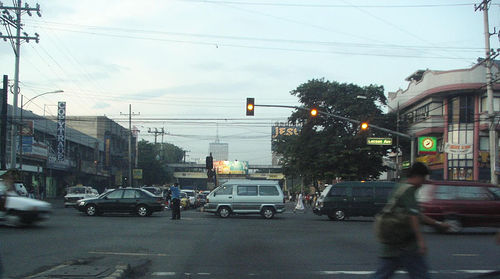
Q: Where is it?
A: This is at the road.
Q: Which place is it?
A: It is a road.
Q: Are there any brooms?
A: No, there are no brooms.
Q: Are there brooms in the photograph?
A: No, there are no brooms.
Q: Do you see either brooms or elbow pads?
A: No, there are no brooms or elbow pads.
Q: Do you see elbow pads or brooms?
A: No, there are no brooms or elbow pads.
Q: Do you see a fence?
A: No, there are no fences.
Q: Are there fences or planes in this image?
A: No, there are no fences or planes.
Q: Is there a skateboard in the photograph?
A: No, there are no skateboards.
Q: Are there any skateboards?
A: No, there are no skateboards.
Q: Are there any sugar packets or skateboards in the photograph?
A: No, there are no skateboards or sugar packets.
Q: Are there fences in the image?
A: No, there are no fences.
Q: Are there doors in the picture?
A: Yes, there is a door.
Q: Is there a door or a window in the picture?
A: Yes, there is a door.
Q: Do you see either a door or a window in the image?
A: Yes, there is a door.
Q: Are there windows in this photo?
A: Yes, there are windows.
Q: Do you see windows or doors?
A: Yes, there are windows.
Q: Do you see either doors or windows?
A: Yes, there are windows.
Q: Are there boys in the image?
A: No, there are no boys.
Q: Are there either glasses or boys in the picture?
A: No, there are no boys or glasses.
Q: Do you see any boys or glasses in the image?
A: No, there are no boys or glasses.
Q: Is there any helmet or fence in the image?
A: No, there are no fences or helmets.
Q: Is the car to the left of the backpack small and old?
A: Yes, the car is small and old.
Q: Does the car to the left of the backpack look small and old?
A: Yes, the car is small and old.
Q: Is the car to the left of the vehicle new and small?
A: No, the car is small but old.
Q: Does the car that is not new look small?
A: Yes, the car is small.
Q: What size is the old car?
A: The car is small.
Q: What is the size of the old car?
A: The car is small.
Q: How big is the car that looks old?
A: The car is small.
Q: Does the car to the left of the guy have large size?
A: No, the car is small.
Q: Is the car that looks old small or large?
A: The car is small.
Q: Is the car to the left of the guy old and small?
A: Yes, the car is old and small.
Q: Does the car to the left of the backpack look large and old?
A: No, the car is old but small.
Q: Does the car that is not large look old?
A: Yes, the car is old.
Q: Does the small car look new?
A: No, the car is old.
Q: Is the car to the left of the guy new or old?
A: The car is old.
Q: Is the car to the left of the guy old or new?
A: The car is old.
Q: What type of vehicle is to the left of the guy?
A: The vehicle is a car.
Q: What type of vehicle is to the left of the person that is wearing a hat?
A: The vehicle is a car.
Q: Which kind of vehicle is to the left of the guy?
A: The vehicle is a car.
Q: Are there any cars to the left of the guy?
A: Yes, there is a car to the left of the guy.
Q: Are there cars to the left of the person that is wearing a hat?
A: Yes, there is a car to the left of the guy.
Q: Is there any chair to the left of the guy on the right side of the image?
A: No, there is a car to the left of the guy.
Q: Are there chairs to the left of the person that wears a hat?
A: No, there is a car to the left of the guy.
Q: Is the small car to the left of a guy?
A: Yes, the car is to the left of a guy.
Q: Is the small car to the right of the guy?
A: No, the car is to the left of the guy.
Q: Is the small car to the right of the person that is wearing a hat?
A: No, the car is to the left of the guy.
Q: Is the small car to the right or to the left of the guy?
A: The car is to the left of the guy.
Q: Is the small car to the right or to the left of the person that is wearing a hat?
A: The car is to the left of the guy.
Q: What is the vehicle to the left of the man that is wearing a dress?
A: The vehicle is a car.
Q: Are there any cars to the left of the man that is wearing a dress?
A: Yes, there is a car to the left of the man.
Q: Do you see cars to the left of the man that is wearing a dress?
A: Yes, there is a car to the left of the man.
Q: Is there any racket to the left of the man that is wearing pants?
A: No, there is a car to the left of the man.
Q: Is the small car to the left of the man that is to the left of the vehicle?
A: Yes, the car is to the left of the man.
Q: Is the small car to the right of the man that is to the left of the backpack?
A: No, the car is to the left of the man.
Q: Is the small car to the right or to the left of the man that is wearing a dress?
A: The car is to the left of the man.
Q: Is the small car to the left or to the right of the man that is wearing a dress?
A: The car is to the left of the man.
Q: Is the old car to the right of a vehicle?
A: No, the car is to the left of a vehicle.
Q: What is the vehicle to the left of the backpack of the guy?
A: The vehicle is a car.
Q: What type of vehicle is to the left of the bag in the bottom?
A: The vehicle is a car.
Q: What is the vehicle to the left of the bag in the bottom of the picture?
A: The vehicle is a car.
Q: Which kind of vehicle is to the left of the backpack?
A: The vehicle is a car.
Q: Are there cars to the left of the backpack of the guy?
A: Yes, there is a car to the left of the backpack.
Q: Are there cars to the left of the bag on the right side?
A: Yes, there is a car to the left of the backpack.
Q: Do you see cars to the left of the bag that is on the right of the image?
A: Yes, there is a car to the left of the backpack.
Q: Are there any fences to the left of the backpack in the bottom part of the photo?
A: No, there is a car to the left of the backpack.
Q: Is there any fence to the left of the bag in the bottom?
A: No, there is a car to the left of the backpack.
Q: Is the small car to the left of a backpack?
A: Yes, the car is to the left of a backpack.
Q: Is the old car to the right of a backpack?
A: No, the car is to the left of a backpack.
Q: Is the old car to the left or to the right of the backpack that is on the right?
A: The car is to the left of the backpack.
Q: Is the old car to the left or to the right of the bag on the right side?
A: The car is to the left of the backpack.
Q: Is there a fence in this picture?
A: No, there are no fences.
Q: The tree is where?
A: The tree is on the roadside.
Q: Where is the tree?
A: The tree is on the roadside.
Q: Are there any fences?
A: No, there are no fences.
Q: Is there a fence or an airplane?
A: No, there are no fences or airplanes.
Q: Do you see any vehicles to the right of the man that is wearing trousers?
A: Yes, there is a vehicle to the right of the man.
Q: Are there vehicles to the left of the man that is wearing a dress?
A: No, the vehicle is to the right of the man.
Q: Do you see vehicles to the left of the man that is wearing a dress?
A: No, the vehicle is to the right of the man.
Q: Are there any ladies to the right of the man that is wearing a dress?
A: No, there is a vehicle to the right of the man.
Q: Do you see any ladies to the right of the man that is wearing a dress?
A: No, there is a vehicle to the right of the man.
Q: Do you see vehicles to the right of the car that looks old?
A: Yes, there is a vehicle to the right of the car.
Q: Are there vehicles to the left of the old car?
A: No, the vehicle is to the right of the car.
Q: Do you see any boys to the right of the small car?
A: No, there is a vehicle to the right of the car.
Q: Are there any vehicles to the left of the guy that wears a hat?
A: Yes, there is a vehicle to the left of the guy.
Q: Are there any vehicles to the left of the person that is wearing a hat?
A: Yes, there is a vehicle to the left of the guy.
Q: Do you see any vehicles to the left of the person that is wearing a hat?
A: Yes, there is a vehicle to the left of the guy.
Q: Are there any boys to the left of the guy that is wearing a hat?
A: No, there is a vehicle to the left of the guy.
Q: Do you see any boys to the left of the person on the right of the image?
A: No, there is a vehicle to the left of the guy.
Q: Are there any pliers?
A: No, there are no pliers.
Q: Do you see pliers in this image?
A: No, there are no pliers.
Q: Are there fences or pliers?
A: No, there are no pliers or fences.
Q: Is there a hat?
A: Yes, there is a hat.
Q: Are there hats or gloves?
A: Yes, there is a hat.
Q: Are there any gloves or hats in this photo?
A: Yes, there is a hat.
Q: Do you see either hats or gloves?
A: Yes, there is a hat.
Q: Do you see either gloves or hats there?
A: Yes, there is a hat.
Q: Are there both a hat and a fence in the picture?
A: No, there is a hat but no fences.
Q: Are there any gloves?
A: No, there are no gloves.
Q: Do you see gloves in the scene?
A: No, there are no gloves.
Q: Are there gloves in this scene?
A: No, there are no gloves.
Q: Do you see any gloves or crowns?
A: No, there are no gloves or crowns.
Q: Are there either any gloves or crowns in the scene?
A: No, there are no gloves or crowns.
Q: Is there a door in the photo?
A: Yes, there are doors.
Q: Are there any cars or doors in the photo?
A: Yes, there are doors.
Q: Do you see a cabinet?
A: No, there are no cabinets.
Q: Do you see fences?
A: No, there are no fences.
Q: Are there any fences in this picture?
A: No, there are no fences.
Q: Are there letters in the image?
A: Yes, there are letters.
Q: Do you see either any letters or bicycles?
A: Yes, there are letters.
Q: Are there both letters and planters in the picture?
A: No, there are letters but no planters.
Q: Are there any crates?
A: No, there are no crates.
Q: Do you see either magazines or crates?
A: No, there are no crates or magazines.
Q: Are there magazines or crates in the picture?
A: No, there are no crates or magazines.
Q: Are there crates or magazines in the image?
A: No, there are no crates or magazines.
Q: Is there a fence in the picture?
A: No, there are no fences.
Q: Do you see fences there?
A: No, there are no fences.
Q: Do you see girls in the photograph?
A: No, there are no girls.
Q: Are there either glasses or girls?
A: No, there are no girls or glasses.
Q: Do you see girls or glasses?
A: No, there are no girls or glasses.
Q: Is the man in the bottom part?
A: Yes, the man is in the bottom of the image.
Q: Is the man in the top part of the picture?
A: No, the man is in the bottom of the image.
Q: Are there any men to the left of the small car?
A: Yes, there is a man to the left of the car.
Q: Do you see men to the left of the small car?
A: Yes, there is a man to the left of the car.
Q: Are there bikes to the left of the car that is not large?
A: No, there is a man to the left of the car.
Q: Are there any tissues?
A: No, there are no tissues.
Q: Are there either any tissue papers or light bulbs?
A: No, there are no tissue papers or light bulbs.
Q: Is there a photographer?
A: No, there are no photographers.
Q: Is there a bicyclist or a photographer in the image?
A: No, there are no photographers or cyclists.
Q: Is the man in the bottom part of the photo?
A: Yes, the man is in the bottom of the image.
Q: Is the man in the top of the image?
A: No, the man is in the bottom of the image.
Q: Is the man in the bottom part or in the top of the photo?
A: The man is in the bottom of the image.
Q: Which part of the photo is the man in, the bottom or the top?
A: The man is in the bottom of the image.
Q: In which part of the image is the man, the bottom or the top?
A: The man is in the bottom of the image.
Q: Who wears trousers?
A: The man wears trousers.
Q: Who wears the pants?
A: The man wears trousers.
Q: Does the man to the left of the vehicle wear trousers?
A: Yes, the man wears trousers.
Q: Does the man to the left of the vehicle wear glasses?
A: No, the man wears trousers.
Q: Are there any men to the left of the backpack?
A: Yes, there is a man to the left of the backpack.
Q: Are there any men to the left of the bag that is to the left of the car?
A: Yes, there is a man to the left of the backpack.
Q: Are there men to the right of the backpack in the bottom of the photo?
A: No, the man is to the left of the backpack.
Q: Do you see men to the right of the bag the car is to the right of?
A: No, the man is to the left of the backpack.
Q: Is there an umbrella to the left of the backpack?
A: No, there is a man to the left of the backpack.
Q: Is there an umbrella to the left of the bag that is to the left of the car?
A: No, there is a man to the left of the backpack.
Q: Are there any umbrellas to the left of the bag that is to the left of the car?
A: No, there is a man to the left of the backpack.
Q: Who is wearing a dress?
A: The man is wearing a dress.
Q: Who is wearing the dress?
A: The man is wearing a dress.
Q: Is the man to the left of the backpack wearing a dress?
A: Yes, the man is wearing a dress.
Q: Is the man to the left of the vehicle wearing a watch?
A: No, the man is wearing a dress.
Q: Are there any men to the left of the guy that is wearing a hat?
A: Yes, there is a man to the left of the guy.